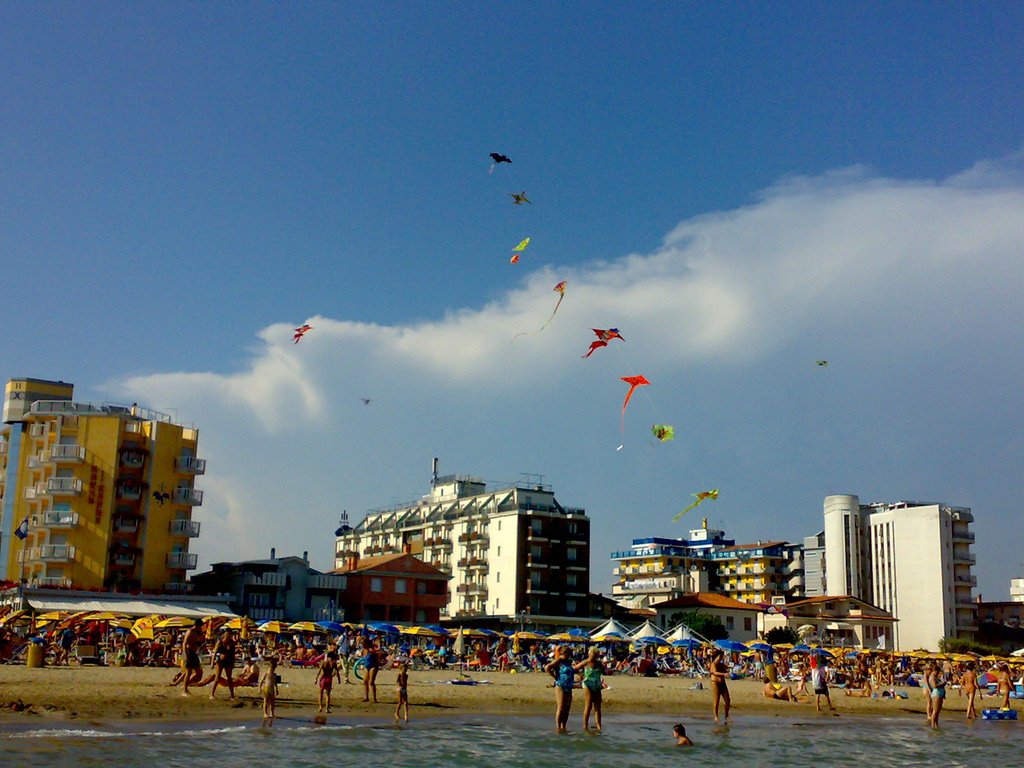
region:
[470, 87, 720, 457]
kites in air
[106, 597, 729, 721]
people walking at beach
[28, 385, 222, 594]
large yellow building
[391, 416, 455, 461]
white clouds in blue sky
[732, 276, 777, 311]
white clouds in blue sky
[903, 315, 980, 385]
white clouds in blue sky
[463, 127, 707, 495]
kites are flying above the beach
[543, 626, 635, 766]
people standing in the water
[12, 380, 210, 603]
yellow building behind the beach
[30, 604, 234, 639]
row of yellow sun umbrellas on the beach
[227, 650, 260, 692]
person sitting on the beach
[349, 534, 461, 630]
red house behind the beach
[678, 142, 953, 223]
edge of white cloud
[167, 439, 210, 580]
balconies on the corner of the yellow building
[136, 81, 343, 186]
The sky is blue.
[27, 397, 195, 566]
The building is yellow.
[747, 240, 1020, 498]
The clouds are coming in.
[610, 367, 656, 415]
The kite is red.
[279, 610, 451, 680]
The umbrellas are blue and yellow.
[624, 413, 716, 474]
The kite is green.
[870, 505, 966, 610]
The building is gray.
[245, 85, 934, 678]
Kites flying in the sky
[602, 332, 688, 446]
The kite is red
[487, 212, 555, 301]
The kite is yellow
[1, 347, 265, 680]
The building is yellow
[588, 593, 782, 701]
The tent top is white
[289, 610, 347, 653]
The umbrella is blue and yellow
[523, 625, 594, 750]
The girl is wearing a blue bathing seat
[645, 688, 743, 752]
The person is in the water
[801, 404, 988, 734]
The building is white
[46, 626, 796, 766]
The sand is on the beach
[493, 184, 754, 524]
group of kites in the sky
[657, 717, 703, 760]
torso of person emerging from ocean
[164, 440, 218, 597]
balconies on yellow building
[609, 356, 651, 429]
orange kite in sky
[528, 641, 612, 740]
two women in swimsuits standing in water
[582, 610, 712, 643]
three white tents on beach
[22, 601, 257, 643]
group of yellow umbrellas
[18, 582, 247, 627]
white awning on yellow building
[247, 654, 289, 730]
child in yellow swim trunks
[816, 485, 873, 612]
cylindrical tower on white building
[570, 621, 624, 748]
Woman wearing green swim suit.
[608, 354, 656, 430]
a small red kite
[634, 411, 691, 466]
a small green kite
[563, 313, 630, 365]
a small red kite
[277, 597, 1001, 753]
a large group of people on a beach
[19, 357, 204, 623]
a yellow building on a beach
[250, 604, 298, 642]
a small yellow and blue umbrella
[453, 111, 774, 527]
a group of kites in the sky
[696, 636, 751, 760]
a person is in the water on the beach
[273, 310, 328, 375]
a small red kite in the sky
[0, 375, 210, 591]
white balconies on a tall yellow building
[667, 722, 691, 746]
person submerged in the water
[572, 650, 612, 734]
woman standing in the water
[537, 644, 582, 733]
woman standing next to woman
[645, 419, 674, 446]
the kite is yellow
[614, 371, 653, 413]
the kite is orange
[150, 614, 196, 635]
yellow beach umbrella next to beach umbrella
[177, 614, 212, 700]
man walking on the beach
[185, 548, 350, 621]
short gray building